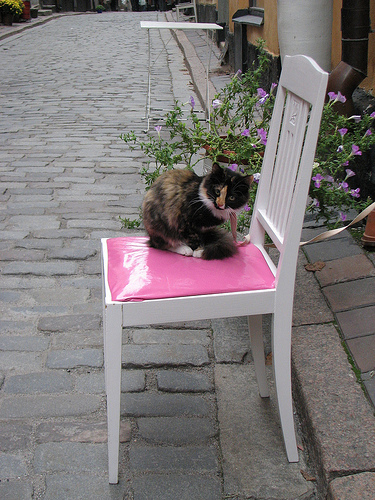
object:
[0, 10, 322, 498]
sidewalk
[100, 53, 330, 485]
chair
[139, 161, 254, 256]
cat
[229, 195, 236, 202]
eye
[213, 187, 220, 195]
eye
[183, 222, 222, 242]
stomach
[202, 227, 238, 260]
tail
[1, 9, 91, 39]
edge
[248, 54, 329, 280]
back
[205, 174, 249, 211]
face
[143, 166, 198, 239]
back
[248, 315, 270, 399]
back leg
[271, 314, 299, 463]
back leg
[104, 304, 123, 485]
front leg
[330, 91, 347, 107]
flower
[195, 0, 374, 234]
wall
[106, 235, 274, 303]
seat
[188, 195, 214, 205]
whiskers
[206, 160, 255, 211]
head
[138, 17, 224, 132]
tray table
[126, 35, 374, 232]
bush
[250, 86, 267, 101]
flower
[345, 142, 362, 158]
flower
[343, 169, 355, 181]
flower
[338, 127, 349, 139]
flower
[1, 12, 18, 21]
pot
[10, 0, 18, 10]
flowers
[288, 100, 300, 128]
design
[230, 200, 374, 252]
leash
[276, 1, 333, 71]
pillar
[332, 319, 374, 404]
grass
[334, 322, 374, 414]
crack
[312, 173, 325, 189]
flower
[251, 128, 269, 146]
flower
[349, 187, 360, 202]
flower